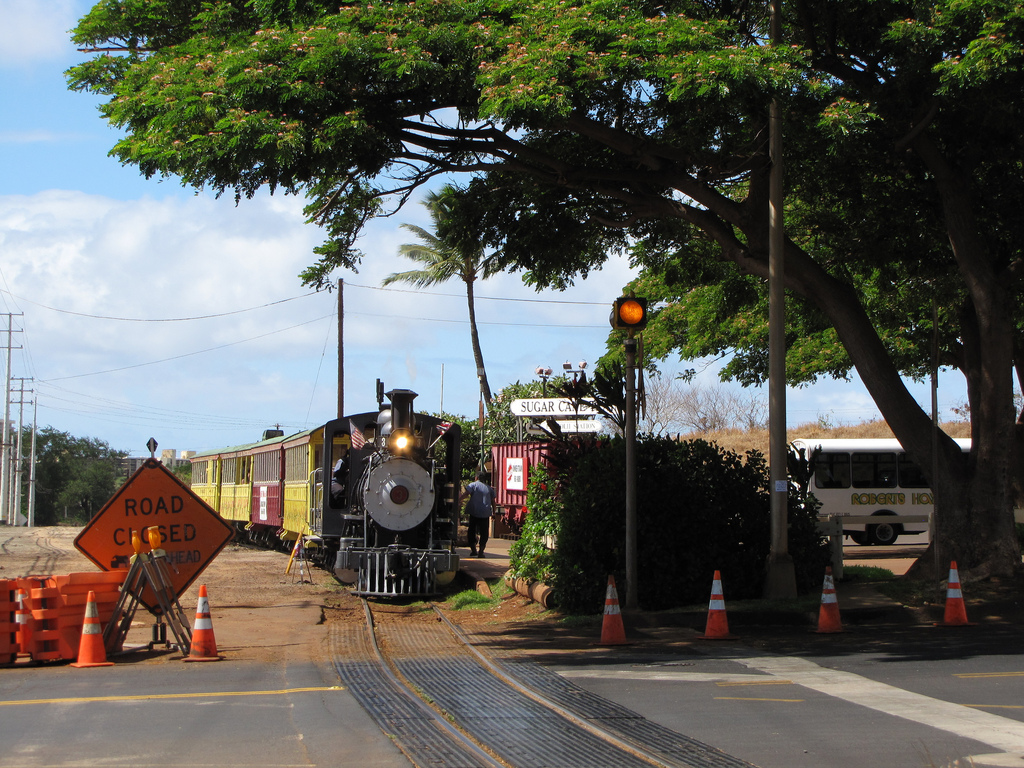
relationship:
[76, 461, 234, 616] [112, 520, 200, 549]
road sign says closed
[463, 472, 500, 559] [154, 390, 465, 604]
person next to train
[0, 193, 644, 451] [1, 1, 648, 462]
clouds are in sky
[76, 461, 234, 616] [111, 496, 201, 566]
road sign has lettering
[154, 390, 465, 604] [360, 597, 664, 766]
train on tracks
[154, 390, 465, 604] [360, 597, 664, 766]
train traveling on tracks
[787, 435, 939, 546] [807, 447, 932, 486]
bus has windows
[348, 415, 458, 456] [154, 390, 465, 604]
flags are on train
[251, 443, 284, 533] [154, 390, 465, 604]
car on train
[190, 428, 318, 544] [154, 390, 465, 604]
cars are on train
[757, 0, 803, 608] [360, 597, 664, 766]
pole by tracks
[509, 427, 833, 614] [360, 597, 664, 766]
bushes are by tracks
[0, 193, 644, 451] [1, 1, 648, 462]
clouds are i n sky